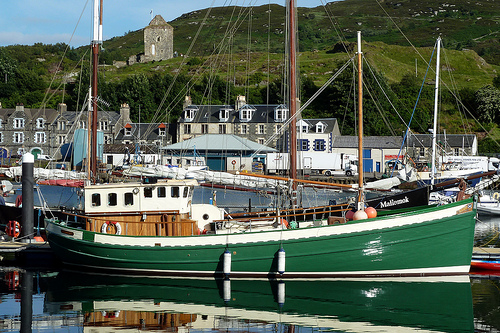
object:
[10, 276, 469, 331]
reflection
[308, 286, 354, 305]
water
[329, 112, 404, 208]
mast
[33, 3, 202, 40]
sky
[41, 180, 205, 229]
housing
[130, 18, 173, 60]
castle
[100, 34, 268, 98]
hill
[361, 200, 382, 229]
ball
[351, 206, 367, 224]
ball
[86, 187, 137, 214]
windows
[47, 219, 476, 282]
boat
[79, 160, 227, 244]
cabin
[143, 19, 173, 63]
buildings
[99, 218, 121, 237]
life buoy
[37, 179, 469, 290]
fishing boat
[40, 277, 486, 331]
water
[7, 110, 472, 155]
building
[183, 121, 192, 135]
window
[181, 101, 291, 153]
building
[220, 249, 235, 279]
weight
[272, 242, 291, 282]
weight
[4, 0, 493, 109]
mountain background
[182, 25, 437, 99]
greenery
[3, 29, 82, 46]
clouds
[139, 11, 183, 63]
structure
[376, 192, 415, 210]
lettering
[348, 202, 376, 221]
buoy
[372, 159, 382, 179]
door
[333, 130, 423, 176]
building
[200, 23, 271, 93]
grass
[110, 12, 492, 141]
surface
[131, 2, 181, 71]
tower